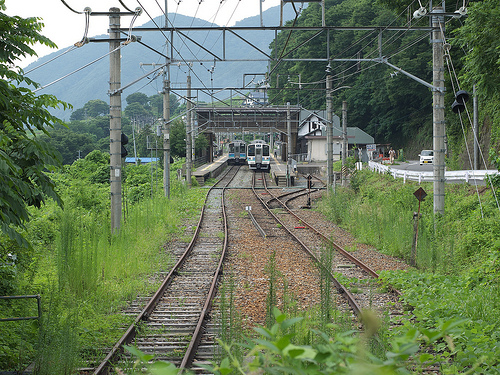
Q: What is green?
A: Tall grass.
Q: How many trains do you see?
A: 2.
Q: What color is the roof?
A: Green.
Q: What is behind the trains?
A: Mountains.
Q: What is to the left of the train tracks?
A: Grass and telephone poles.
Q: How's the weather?
A: It's cloudy.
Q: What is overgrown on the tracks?
A: Weeds and grass.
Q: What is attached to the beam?
A: Electrical wires.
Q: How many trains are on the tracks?
A: Two.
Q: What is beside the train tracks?
A: Green grass.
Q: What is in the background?
A: Mountains.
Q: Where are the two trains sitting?
A: Beside the train station.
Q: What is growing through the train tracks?
A: Grass.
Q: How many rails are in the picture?
A: Two.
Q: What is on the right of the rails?
A: Weeds.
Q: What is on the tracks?
A: Trains.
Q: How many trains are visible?
A: Two.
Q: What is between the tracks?
A: Pebbles.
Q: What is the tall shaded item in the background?
A: A mountain.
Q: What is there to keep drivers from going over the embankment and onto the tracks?
A: A white fence.